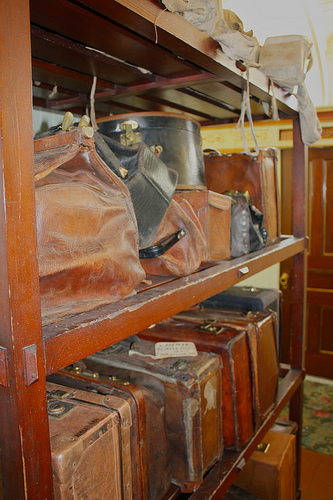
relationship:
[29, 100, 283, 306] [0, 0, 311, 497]
luggage on wooden rack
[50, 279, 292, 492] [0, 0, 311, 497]
luggage on wooden rack